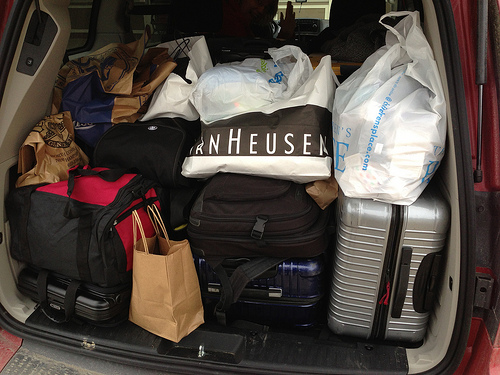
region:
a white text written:
[158, 113, 368, 192]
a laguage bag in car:
[333, 188, 461, 353]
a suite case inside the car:
[333, 198, 472, 363]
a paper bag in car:
[118, 235, 250, 361]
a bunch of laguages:
[42, 35, 447, 367]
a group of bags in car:
[20, 55, 455, 372]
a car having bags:
[25, 25, 457, 362]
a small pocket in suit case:
[321, 27, 474, 234]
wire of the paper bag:
[121, 212, 161, 257]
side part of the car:
[8, 13, 83, 78]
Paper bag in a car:
[127, 230, 235, 360]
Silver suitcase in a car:
[335, 184, 446, 349]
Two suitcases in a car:
[179, 191, 333, 324]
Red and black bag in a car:
[14, 177, 159, 282]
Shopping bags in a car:
[190, 62, 325, 172]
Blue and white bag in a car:
[346, 30, 456, 210]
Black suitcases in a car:
[90, 119, 194, 183]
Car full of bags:
[52, 41, 473, 353]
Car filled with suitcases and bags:
[40, 47, 429, 354]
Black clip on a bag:
[244, 218, 286, 240]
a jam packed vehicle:
[26, 22, 453, 367]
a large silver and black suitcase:
[314, 173, 436, 373]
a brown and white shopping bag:
[173, 81, 338, 188]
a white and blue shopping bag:
[311, 26, 441, 213]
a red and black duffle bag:
[21, 153, 152, 292]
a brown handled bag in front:
[120, 188, 212, 353]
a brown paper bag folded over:
[1, 82, 106, 197]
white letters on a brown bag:
[186, 123, 343, 168]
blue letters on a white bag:
[326, 56, 413, 188]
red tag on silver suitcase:
[372, 263, 396, 315]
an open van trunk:
[0, 5, 492, 373]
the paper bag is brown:
[128, 207, 201, 338]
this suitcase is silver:
[330, 180, 442, 355]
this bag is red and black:
[18, 160, 165, 282]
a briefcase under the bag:
[14, 264, 121, 330]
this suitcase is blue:
[192, 254, 323, 322]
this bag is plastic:
[185, 49, 329, 179]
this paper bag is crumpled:
[50, 43, 155, 118]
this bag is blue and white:
[321, 7, 446, 202]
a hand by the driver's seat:
[275, 2, 300, 52]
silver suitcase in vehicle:
[340, 193, 424, 333]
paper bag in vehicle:
[121, 240, 209, 337]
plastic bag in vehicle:
[336, 9, 434, 196]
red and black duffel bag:
[8, 163, 159, 271]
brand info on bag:
[188, 125, 334, 165]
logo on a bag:
[33, 113, 80, 147]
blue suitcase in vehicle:
[191, 255, 316, 327]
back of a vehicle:
[0, 2, 477, 370]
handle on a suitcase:
[383, 245, 416, 317]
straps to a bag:
[203, 253, 275, 321]